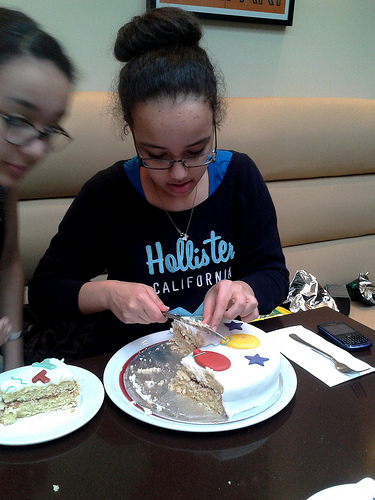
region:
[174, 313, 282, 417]
the cake is half cut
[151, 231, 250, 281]
holister writing is on the shirt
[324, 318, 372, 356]
the phone is on the counter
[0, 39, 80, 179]
the woman has glasses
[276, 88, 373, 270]
the sofa is brown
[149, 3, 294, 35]
painting is on the wall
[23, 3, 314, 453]
A young girl slicing a cake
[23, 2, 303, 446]
A young girl slicing a cake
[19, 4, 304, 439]
A young girl slicing a cake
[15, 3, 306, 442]
A young girl slicing a cake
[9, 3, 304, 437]
A young girl slicing a cake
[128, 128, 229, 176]
a person wearing eyeglasses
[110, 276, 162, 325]
the hand of a person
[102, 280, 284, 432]
a person cutting cake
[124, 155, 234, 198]
a person wearing a blue shirt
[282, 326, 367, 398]
a metal fork on a white napkin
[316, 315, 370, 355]
a cellular phone on a table top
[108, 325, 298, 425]
a cake on a white plate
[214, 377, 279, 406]
white frosting on a cake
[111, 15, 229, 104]
person with black hair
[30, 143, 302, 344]
THE GIRL IS WEARING A BLACK SHIRT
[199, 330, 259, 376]
THE BALLOONS ARE ON THE CAKE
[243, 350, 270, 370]
THE STAR IS ON THE CAKE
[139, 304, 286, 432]
THE GIRL IS CUTTING THE CAKE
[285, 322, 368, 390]
THE FORK IS ON THE NAPKIN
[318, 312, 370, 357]
THE CELL PHONE IS ON THE TABLE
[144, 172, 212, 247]
THE GIRL IS WEARING A NECKLACE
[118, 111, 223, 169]
THE GIRL IS WEARING GLASSES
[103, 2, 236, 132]
THE GIRL HAS A BUN IN HER HAIR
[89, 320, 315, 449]
THE CAKE IS ON THE PLATE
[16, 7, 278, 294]
two young girls getting cake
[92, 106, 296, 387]
she is taking cake off of the knife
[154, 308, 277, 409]
this cake had stars and a balloon on it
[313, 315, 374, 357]
a cellphone on the table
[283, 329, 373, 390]
a fork on the table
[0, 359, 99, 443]
this is a double layered cake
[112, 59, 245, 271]
this is a young lady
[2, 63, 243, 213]
they are both wearing glasses on their face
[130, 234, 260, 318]
this is the name of the advertisement on her shirt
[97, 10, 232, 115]
her hair is in a bun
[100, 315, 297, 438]
Circular plate with cake on it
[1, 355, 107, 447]
Piece of cake on plate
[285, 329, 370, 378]
Fork on top of napkin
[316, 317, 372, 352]
Cell phone on table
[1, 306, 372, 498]
Dark wooden table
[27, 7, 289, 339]
Girl cutting a cake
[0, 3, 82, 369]
Girl wearing glasses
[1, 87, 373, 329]
Back of table bench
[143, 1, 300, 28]
Part of picture frame on wall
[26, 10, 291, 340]
Girl wearing a black shirt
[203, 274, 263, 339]
Hand of a woman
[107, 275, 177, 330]
Hand of a woman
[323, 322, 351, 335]
Screen on a cellphone